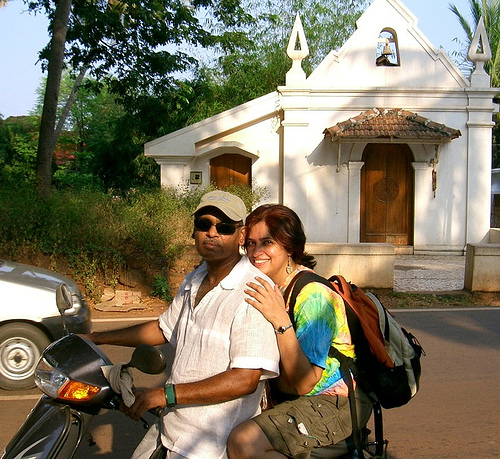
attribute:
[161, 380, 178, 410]
wristband — greenish wrist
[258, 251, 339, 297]
shoulder — her 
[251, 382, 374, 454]
shorts — cargo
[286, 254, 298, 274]
earring — hanging down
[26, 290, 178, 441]
scooter — silver  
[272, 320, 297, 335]
watch — thin wrist 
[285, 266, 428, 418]
bag — beige book, black, orange, 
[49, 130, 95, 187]
roof — partly visible 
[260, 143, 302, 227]
floor — light brown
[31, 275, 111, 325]
car — silver, front end 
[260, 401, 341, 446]
shorts — khaki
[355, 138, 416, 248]
door — wooden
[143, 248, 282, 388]
shirt — white 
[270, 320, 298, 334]
watch — silver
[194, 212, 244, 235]
shades — Dark 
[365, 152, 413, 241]
door — brown,  decoration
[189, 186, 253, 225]
cap. — ball 